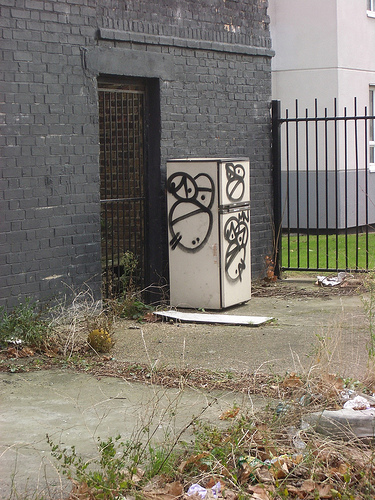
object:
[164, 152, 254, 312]
refrigerator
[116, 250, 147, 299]
weeds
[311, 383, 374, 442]
trash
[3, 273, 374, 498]
sidewalk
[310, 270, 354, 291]
trash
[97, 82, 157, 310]
grate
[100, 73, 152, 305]
door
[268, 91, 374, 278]
gate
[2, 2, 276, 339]
wall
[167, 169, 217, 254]
graffiti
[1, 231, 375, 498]
ground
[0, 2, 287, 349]
building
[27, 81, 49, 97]
brick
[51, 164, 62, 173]
brick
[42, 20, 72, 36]
brick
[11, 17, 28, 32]
brick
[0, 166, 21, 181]
brick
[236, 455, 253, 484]
leaves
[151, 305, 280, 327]
cardboard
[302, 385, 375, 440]
bag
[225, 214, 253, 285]
graffiti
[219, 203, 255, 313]
door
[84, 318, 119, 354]
ball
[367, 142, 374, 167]
window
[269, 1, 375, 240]
building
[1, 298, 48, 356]
shrub